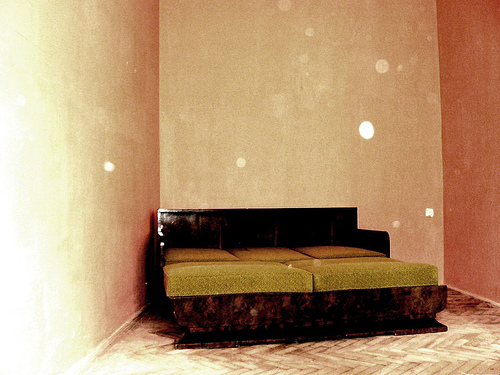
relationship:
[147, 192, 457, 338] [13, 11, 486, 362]
bed inside room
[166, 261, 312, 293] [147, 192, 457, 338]
cushion on top of bed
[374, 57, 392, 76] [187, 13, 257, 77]
spot across wall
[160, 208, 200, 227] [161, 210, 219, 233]
light across wood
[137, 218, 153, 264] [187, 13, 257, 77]
shadow across wall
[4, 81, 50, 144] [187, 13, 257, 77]
light across wall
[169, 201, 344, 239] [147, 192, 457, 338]
headboard attached to bed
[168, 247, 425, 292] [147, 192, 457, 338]
mattress across bed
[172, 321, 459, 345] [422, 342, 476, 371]
carpet on top of ground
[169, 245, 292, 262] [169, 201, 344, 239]
pillows against headboard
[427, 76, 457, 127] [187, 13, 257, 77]
corner of a wall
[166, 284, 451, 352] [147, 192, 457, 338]
foot board of bed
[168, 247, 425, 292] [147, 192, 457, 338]
couch on top of bed